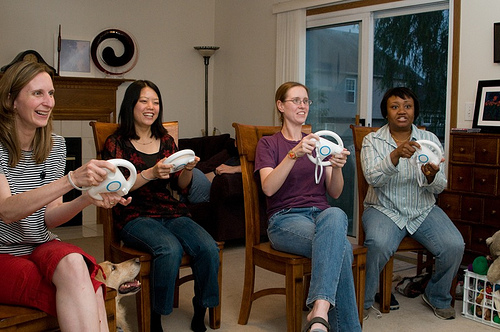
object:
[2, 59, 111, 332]
woman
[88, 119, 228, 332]
chair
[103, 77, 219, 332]
woman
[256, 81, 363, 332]
woman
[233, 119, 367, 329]
chair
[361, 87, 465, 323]
woman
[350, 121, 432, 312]
chair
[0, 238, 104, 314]
shorts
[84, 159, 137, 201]
game controller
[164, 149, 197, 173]
game controller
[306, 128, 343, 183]
game controller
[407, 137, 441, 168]
game controller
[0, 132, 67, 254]
shirt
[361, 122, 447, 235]
shirt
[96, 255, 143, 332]
dog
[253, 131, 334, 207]
tee shirt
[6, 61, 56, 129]
head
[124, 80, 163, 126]
head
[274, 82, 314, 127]
head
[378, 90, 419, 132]
head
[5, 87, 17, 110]
ear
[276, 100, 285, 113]
ear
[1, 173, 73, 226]
arm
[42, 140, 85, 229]
arm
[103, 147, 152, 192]
arm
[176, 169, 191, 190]
arm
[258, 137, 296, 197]
arm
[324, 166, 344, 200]
arm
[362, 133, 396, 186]
arm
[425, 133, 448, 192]
arm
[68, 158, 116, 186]
hand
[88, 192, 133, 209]
hand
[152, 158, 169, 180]
hand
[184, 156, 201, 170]
hand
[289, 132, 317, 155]
hand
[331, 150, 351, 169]
hand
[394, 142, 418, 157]
hand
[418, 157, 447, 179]
hand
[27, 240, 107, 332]
legs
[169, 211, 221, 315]
legs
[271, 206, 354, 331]
legs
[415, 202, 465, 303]
legs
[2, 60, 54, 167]
hair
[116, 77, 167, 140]
hair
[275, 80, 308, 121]
hair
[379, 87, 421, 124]
hair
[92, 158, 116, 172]
fingers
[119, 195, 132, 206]
fingers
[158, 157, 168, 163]
fingers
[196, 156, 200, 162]
fingers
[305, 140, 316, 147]
fingers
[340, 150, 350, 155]
fingers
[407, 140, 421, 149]
fingers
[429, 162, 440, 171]
fingers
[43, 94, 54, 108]
nose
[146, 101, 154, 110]
nose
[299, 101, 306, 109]
nose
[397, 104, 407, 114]
nose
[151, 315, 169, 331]
feet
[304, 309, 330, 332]
feet